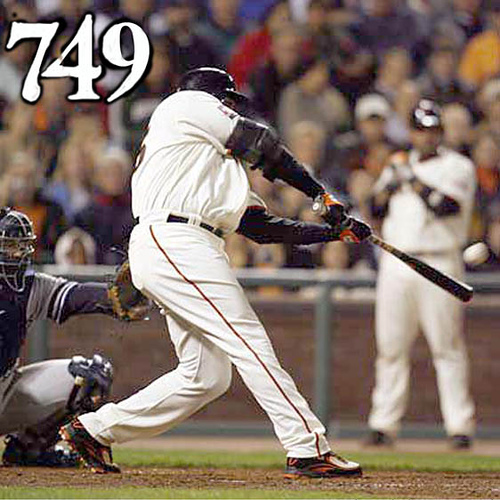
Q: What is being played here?
A: Baseball.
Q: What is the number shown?
A: Seven four nine.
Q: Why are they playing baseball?
A: Conpetition.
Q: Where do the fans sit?
A: Stands.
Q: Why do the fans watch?
A: Entertainment.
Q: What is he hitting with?
A: Bat.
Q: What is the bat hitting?
A: Ball.